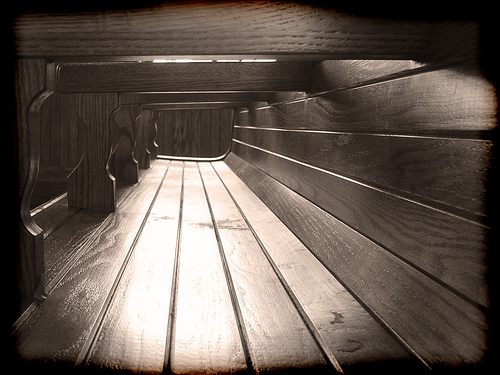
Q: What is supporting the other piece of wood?
A: Wood.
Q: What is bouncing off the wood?
A: Light.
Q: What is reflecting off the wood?
A: Light.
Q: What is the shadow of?
A: Wood.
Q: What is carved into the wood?
A: A design.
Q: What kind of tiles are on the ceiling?
A: Wooden titles.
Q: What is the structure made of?
A: Wood.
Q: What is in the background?
A: Wall of wood.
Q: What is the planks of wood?
A: Vertical.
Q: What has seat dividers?
A: The wooden bench.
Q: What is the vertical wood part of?
A: The seat divider.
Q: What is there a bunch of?
A: Wood planks.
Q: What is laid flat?
A: The wood planks.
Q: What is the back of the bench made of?
A: Wooden planks.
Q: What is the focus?
A: Wood bench.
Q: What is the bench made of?
A: Wood.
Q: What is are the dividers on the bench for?
A: Hand rests.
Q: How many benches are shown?
A: 1.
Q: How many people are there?
A: 0.